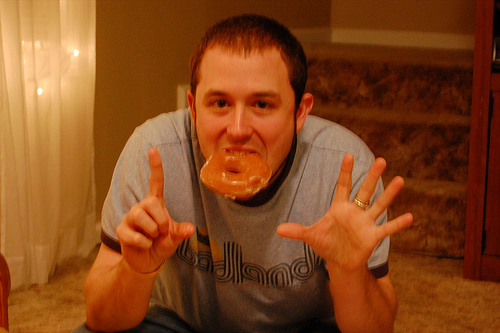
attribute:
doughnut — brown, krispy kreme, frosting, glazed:
[196, 146, 272, 207]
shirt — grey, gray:
[90, 101, 395, 330]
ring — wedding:
[352, 192, 369, 209]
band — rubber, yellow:
[121, 257, 167, 275]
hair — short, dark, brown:
[179, 8, 308, 108]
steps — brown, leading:
[276, 32, 478, 277]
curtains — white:
[1, 1, 102, 289]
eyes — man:
[250, 95, 275, 114]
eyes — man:
[207, 95, 232, 115]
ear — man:
[294, 90, 316, 134]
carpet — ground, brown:
[5, 215, 497, 332]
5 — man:
[271, 150, 418, 277]